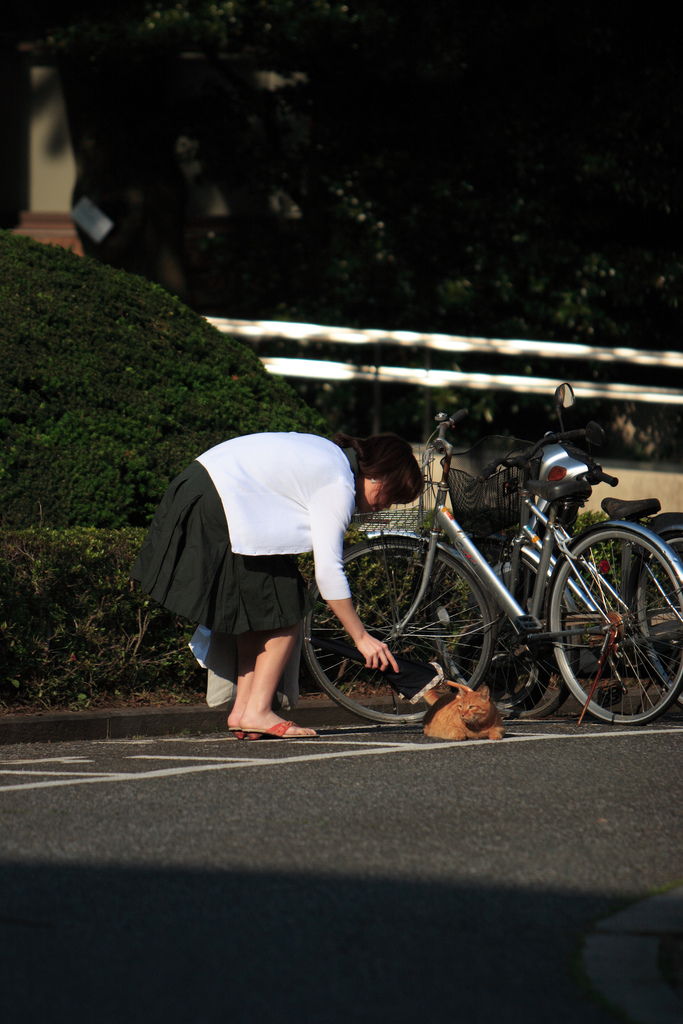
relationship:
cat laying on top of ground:
[424, 686, 506, 740] [33, 663, 650, 918]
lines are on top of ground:
[0, 728, 683, 792] [9, 699, 636, 901]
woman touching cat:
[130, 431, 425, 740] [408, 670, 506, 735]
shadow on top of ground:
[20, 819, 662, 997] [20, 740, 649, 942]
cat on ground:
[424, 686, 506, 740] [0, 719, 683, 1024]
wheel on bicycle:
[541, 512, 681, 736] [301, 410, 683, 727]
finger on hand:
[387, 651, 403, 680] [350, 631, 409, 679]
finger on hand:
[361, 656, 372, 669] [351, 638, 409, 685]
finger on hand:
[371, 652, 383, 673] [344, 638, 409, 680]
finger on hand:
[372, 647, 390, 674] [352, 635, 406, 683]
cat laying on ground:
[424, 686, 506, 740] [0, 719, 683, 1024]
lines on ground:
[2, 722, 681, 781] [0, 719, 683, 1024]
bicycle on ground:
[301, 410, 683, 727] [0, 719, 683, 1024]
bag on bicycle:
[424, 445, 537, 553] [301, 410, 683, 727]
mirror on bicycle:
[526, 362, 591, 422] [436, 366, 683, 724]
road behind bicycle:
[118, 298, 678, 542] [301, 410, 683, 727]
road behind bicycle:
[118, 298, 678, 542] [436, 366, 683, 724]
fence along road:
[202, 315, 683, 404] [308, 431, 683, 611]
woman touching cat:
[123, 421, 443, 761] [412, 672, 527, 756]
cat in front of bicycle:
[412, 680, 521, 750] [285, 367, 678, 738]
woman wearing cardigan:
[123, 421, 443, 761] [181, 424, 368, 618]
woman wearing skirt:
[123, 421, 443, 761] [109, 449, 327, 657]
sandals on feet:
[226, 718, 315, 746] [218, 705, 326, 748]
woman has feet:
[130, 431, 425, 740] [218, 705, 326, 748]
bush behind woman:
[1, 208, 390, 540] [123, 421, 443, 761]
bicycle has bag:
[419, 375, 682, 732] [440, 435, 544, 537]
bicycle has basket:
[294, 429, 681, 745] [350, 466, 460, 560]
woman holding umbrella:
[130, 431, 425, 740] [290, 604, 489, 741]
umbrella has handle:
[287, 621, 480, 717] [423, 662, 490, 702]